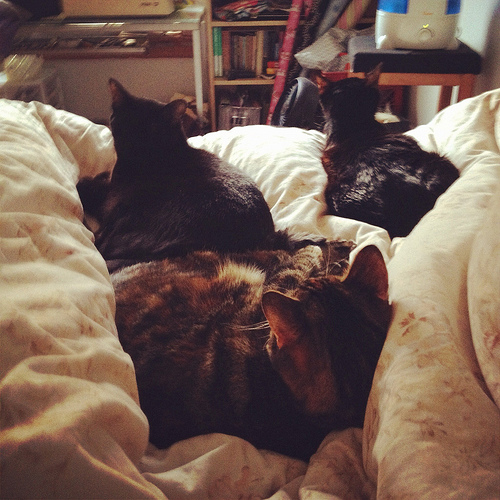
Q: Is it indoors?
A: Yes, it is indoors.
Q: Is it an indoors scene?
A: Yes, it is indoors.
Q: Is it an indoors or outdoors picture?
A: It is indoors.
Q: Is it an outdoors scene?
A: No, it is indoors.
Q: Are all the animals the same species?
A: Yes, all the animals are cats.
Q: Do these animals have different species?
A: No, all the animals are cats.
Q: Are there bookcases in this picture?
A: Yes, there is a bookcase.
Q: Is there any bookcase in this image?
A: Yes, there is a bookcase.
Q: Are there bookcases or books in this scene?
A: Yes, there is a bookcase.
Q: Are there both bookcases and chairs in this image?
A: No, there is a bookcase but no chairs.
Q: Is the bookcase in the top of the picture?
A: Yes, the bookcase is in the top of the image.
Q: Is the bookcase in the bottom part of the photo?
A: No, the bookcase is in the top of the image.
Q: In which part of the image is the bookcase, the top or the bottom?
A: The bookcase is in the top of the image.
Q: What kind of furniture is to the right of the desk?
A: The piece of furniture is a bookcase.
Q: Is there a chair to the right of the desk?
A: No, there is a bookcase to the right of the desk.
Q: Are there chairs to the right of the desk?
A: No, there is a bookcase to the right of the desk.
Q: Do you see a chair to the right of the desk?
A: No, there is a bookcase to the right of the desk.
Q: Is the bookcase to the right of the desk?
A: Yes, the bookcase is to the right of the desk.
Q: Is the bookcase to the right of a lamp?
A: No, the bookcase is to the right of the desk.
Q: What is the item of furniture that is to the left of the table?
A: The piece of furniture is a bookcase.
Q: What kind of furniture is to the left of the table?
A: The piece of furniture is a bookcase.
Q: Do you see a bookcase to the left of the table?
A: Yes, there is a bookcase to the left of the table.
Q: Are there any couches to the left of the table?
A: No, there is a bookcase to the left of the table.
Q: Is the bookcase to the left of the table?
A: Yes, the bookcase is to the left of the table.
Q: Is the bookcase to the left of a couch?
A: No, the bookcase is to the left of the table.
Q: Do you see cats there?
A: Yes, there is a cat.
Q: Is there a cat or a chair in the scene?
A: Yes, there is a cat.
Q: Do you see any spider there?
A: No, there are no spiders.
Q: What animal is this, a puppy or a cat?
A: This is a cat.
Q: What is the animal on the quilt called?
A: The animal is a cat.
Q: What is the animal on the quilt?
A: The animal is a cat.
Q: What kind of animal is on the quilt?
A: The animal is a cat.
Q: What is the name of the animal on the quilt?
A: The animal is a cat.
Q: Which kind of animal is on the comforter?
A: The animal is a cat.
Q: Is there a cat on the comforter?
A: Yes, there is a cat on the comforter.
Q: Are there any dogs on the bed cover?
A: No, there is a cat on the bed cover.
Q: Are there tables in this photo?
A: Yes, there is a table.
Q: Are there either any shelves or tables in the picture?
A: Yes, there is a table.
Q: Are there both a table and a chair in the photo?
A: No, there is a table but no chairs.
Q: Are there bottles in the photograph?
A: No, there are no bottles.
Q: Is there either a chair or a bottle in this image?
A: No, there are no bottles or chairs.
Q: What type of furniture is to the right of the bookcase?
A: The piece of furniture is a table.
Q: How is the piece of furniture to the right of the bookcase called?
A: The piece of furniture is a table.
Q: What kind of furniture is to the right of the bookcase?
A: The piece of furniture is a table.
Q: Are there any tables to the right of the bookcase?
A: Yes, there is a table to the right of the bookcase.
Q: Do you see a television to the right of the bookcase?
A: No, there is a table to the right of the bookcase.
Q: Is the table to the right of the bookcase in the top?
A: Yes, the table is to the right of the bookcase.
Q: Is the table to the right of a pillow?
A: No, the table is to the right of the bookcase.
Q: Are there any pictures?
A: No, there are no pictures.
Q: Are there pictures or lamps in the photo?
A: No, there are no pictures or lamps.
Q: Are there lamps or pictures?
A: No, there are no pictures or lamps.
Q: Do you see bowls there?
A: No, there are no bowls.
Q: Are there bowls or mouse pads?
A: No, there are no bowls or mouse pads.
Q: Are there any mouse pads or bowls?
A: No, there are no bowls or mouse pads.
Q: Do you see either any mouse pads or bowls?
A: No, there are no bowls or mouse pads.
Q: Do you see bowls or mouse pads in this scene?
A: No, there are no bowls or mouse pads.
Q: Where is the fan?
A: The fan is on the floor.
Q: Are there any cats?
A: Yes, there is a cat.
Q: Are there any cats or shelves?
A: Yes, there is a cat.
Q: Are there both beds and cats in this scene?
A: Yes, there are both a cat and a bed.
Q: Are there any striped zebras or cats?
A: Yes, there is a striped cat.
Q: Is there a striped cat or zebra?
A: Yes, there is a striped cat.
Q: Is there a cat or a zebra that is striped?
A: Yes, the cat is striped.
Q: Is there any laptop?
A: No, there are no laptops.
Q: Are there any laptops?
A: No, there are no laptops.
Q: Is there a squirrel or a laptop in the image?
A: No, there are no laptops or squirrels.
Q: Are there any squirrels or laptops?
A: No, there are no laptops or squirrels.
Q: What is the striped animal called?
A: The animal is a cat.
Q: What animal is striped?
A: The animal is a cat.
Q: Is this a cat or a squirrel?
A: This is a cat.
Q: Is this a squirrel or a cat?
A: This is a cat.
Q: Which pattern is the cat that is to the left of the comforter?
A: The cat is striped.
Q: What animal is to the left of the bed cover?
A: The animal is a cat.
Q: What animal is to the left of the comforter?
A: The animal is a cat.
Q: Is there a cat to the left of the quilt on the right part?
A: Yes, there is a cat to the left of the comforter.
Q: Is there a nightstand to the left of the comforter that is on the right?
A: No, there is a cat to the left of the quilt.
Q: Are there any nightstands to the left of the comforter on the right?
A: No, there is a cat to the left of the quilt.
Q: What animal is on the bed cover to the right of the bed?
A: The cat is on the comforter.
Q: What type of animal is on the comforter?
A: The animal is a cat.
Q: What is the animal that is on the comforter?
A: The animal is a cat.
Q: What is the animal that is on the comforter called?
A: The animal is a cat.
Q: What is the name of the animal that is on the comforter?
A: The animal is a cat.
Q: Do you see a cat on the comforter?
A: Yes, there is a cat on the comforter.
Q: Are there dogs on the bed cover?
A: No, there is a cat on the bed cover.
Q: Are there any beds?
A: Yes, there is a bed.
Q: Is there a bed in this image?
A: Yes, there is a bed.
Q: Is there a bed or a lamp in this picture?
A: Yes, there is a bed.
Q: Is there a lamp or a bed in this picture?
A: Yes, there is a bed.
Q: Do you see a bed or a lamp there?
A: Yes, there is a bed.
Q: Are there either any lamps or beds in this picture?
A: Yes, there is a bed.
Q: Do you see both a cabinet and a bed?
A: No, there is a bed but no cabinets.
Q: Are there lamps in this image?
A: No, there are no lamps.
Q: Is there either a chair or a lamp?
A: No, there are no lamps or chairs.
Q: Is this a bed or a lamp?
A: This is a bed.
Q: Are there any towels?
A: No, there are no towels.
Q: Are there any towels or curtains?
A: No, there are no towels or curtains.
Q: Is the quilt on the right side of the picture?
A: Yes, the quilt is on the right of the image.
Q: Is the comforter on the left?
A: No, the comforter is on the right of the image.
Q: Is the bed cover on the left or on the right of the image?
A: The bed cover is on the right of the image.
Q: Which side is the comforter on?
A: The comforter is on the right of the image.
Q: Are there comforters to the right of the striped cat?
A: Yes, there is a comforter to the right of the cat.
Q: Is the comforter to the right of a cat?
A: Yes, the comforter is to the right of a cat.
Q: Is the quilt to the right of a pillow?
A: No, the quilt is to the right of a cat.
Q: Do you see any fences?
A: No, there are no fences.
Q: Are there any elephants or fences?
A: No, there are no fences or elephants.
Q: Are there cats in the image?
A: Yes, there is a cat.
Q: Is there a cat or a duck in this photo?
A: Yes, there is a cat.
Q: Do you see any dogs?
A: No, there are no dogs.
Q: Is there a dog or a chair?
A: No, there are no dogs or chairs.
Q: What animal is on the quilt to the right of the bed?
A: The cat is on the bed cover.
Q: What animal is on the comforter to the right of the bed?
A: The animal is a cat.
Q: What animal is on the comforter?
A: The animal is a cat.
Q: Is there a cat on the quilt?
A: Yes, there is a cat on the quilt.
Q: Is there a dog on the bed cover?
A: No, there is a cat on the bed cover.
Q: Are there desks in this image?
A: Yes, there is a desk.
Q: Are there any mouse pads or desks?
A: Yes, there is a desk.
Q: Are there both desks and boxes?
A: No, there is a desk but no boxes.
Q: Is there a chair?
A: No, there are no chairs.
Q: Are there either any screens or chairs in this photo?
A: No, there are no chairs or screens.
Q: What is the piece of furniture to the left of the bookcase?
A: The piece of furniture is a desk.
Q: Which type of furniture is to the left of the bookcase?
A: The piece of furniture is a desk.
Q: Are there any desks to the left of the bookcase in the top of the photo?
A: Yes, there is a desk to the left of the bookcase.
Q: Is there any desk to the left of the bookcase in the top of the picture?
A: Yes, there is a desk to the left of the bookcase.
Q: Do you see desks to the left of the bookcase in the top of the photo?
A: Yes, there is a desk to the left of the bookcase.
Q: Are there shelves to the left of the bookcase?
A: No, there is a desk to the left of the bookcase.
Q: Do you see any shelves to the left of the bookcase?
A: No, there is a desk to the left of the bookcase.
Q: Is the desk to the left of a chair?
A: No, the desk is to the left of a bookcase.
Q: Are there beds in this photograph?
A: Yes, there is a bed.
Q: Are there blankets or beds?
A: Yes, there is a bed.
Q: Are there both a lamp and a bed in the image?
A: No, there is a bed but no lamps.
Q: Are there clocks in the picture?
A: No, there are no clocks.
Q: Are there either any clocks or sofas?
A: No, there are no clocks or sofas.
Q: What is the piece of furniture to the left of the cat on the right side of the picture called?
A: The piece of furniture is a bed.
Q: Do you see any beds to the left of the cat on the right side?
A: Yes, there is a bed to the left of the cat.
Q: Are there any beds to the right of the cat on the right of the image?
A: No, the bed is to the left of the cat.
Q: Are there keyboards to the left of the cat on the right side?
A: No, there is a bed to the left of the cat.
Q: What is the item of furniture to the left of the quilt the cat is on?
A: The piece of furniture is a bed.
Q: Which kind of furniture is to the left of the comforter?
A: The piece of furniture is a bed.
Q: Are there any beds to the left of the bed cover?
A: Yes, there is a bed to the left of the bed cover.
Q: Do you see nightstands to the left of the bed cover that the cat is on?
A: No, there is a bed to the left of the quilt.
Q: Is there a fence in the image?
A: No, there are no fences.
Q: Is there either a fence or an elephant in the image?
A: No, there are no fences or elephants.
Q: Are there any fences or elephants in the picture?
A: No, there are no fences or elephants.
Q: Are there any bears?
A: No, there are no bears.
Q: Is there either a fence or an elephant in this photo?
A: No, there are no fences or elephants.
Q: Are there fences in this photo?
A: No, there are no fences.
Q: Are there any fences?
A: No, there are no fences.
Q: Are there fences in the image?
A: No, there are no fences.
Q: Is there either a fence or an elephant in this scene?
A: No, there are no fences or elephants.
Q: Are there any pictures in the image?
A: No, there are no pictures.